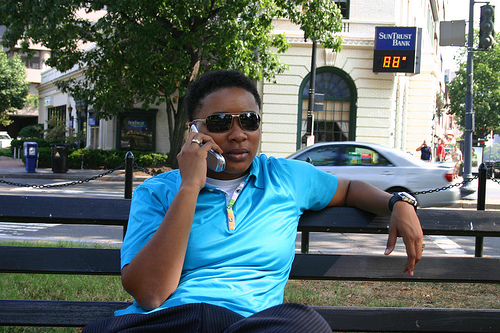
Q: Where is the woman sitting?
A: On a bench.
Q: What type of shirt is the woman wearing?
A: A light blue shirt.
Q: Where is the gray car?
A: Driving down the street.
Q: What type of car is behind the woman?
A: Silver four door sedan.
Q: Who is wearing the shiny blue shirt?
A: The woman on the bench.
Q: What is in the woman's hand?
A: A cell phone.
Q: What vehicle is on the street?
A: A silver car.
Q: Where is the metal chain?
A: On the posts in the ground.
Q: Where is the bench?
A: By the sidewalk.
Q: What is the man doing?
A: Sitting on the bench.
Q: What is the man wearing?
A: A light blue polo shirt.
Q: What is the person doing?
A: Talking on the phone.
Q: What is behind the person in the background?
A: A moving silver sedan.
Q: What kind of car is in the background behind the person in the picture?
A: A silver four-door car.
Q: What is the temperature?
A: 88 degrees.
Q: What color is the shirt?
A: Blue.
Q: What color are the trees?
A: Green.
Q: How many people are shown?
A: One.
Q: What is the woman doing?
A: Talking on phone.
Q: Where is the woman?
A: On bench.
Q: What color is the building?
A: White.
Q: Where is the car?
A: On road.